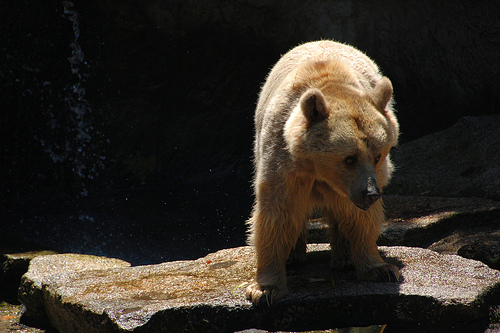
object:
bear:
[243, 38, 407, 307]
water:
[45, 0, 117, 250]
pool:
[0, 192, 499, 332]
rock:
[20, 242, 499, 333]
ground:
[0, 173, 500, 332]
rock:
[0, 246, 59, 308]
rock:
[299, 111, 499, 201]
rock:
[292, 189, 499, 249]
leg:
[243, 167, 319, 308]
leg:
[325, 186, 402, 283]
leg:
[322, 205, 353, 274]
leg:
[287, 207, 311, 269]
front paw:
[357, 260, 405, 284]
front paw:
[244, 281, 289, 310]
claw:
[385, 269, 392, 283]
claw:
[270, 286, 278, 305]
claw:
[263, 289, 273, 308]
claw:
[389, 265, 400, 282]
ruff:
[292, 56, 367, 105]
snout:
[347, 166, 381, 211]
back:
[253, 39, 392, 111]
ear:
[369, 76, 394, 110]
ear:
[299, 88, 329, 123]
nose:
[366, 176, 382, 201]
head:
[283, 75, 398, 213]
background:
[2, 0, 499, 268]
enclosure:
[2, 1, 499, 332]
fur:
[294, 62, 361, 129]